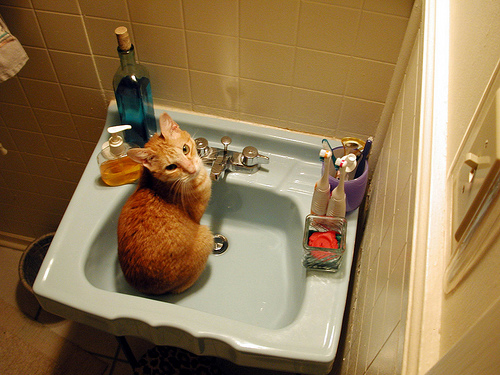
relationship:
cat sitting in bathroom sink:
[116, 110, 213, 296] [26, 91, 360, 373]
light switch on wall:
[451, 86, 499, 239] [439, 13, 498, 363]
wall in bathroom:
[439, 13, 498, 363] [5, 2, 498, 370]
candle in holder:
[307, 229, 339, 262] [299, 212, 351, 279]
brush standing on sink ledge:
[323, 156, 346, 218] [287, 164, 359, 369]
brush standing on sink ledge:
[311, 148, 333, 217] [287, 164, 359, 369]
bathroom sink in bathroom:
[26, 91, 360, 373] [5, 2, 498, 370]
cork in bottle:
[115, 21, 131, 51] [107, 25, 162, 145]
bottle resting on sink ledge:
[107, 25, 162, 145] [32, 95, 362, 373]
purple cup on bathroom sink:
[321, 163, 371, 215] [26, 91, 360, 373]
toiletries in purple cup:
[320, 134, 378, 180] [321, 163, 371, 215]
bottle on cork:
[107, 25, 162, 148] [110, 21, 132, 51]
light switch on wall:
[451, 60, 500, 243] [341, 8, 498, 373]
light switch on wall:
[446, 57, 498, 251] [341, 8, 498, 373]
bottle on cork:
[107, 25, 162, 145] [111, 25, 134, 52]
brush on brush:
[323, 156, 346, 218] [305, 141, 332, 217]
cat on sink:
[95, 133, 233, 285] [88, 137, 492, 368]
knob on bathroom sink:
[194, 133, 211, 149] [26, 91, 360, 373]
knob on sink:
[241, 147, 273, 175] [38, 72, 373, 350]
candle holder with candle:
[301, 210, 348, 277] [307, 230, 339, 257]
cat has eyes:
[116, 110, 213, 296] [163, 141, 194, 174]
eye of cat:
[163, 162, 178, 177] [116, 110, 213, 296]